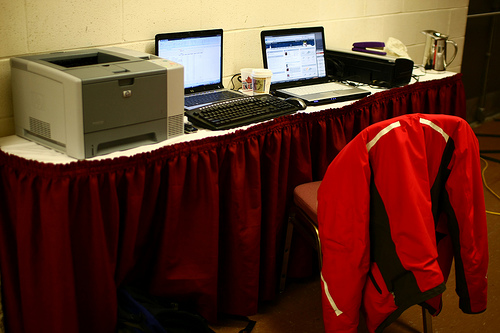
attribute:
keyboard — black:
[185, 94, 304, 130]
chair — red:
[283, 118, 484, 330]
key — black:
[209, 109, 214, 113]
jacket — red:
[315, 110, 496, 331]